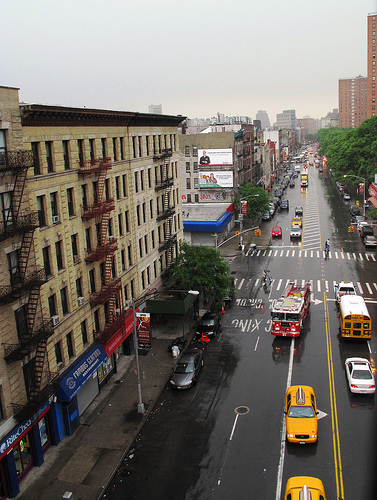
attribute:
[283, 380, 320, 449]
cab — yellow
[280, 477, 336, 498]
cab — yellow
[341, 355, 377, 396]
car — white, gray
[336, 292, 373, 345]
school bus — yellow, white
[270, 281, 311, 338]
fire truck — red, white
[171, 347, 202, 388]
car — gray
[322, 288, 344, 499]
yellow lines — solid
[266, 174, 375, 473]
street — wet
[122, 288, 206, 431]
light — metal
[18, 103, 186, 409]
apartments — five stories, building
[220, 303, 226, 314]
traffic cone — orange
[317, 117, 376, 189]
trees — green, bushy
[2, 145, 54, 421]
fire escape — black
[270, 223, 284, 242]
car — red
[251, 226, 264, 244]
traffic light — red